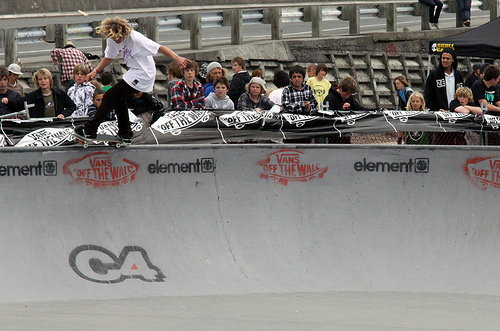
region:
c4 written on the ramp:
[37, 220, 212, 330]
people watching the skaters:
[167, 52, 378, 139]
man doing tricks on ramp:
[86, 10, 168, 170]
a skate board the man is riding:
[60, 119, 160, 151]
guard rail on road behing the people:
[154, 12, 334, 42]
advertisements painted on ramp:
[60, 155, 198, 193]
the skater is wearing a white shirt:
[100, 38, 157, 97]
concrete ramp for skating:
[173, 192, 419, 299]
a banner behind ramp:
[184, 117, 306, 138]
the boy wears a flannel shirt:
[172, 75, 204, 112]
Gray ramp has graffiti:
[1, 148, 498, 328]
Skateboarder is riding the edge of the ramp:
[69, 14, 190, 151]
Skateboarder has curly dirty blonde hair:
[93, 13, 134, 43]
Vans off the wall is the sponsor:
[255, 145, 332, 187]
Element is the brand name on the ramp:
[145, 157, 220, 181]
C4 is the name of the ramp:
[64, 245, 166, 286]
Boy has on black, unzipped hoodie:
[423, 49, 470, 106]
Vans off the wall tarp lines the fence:
[3, 105, 499, 155]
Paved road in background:
[0, 14, 499, 46]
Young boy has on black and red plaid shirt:
[169, 76, 209, 111]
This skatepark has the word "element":
[151, 149, 223, 211]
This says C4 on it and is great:
[75, 235, 157, 313]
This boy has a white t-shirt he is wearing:
[121, 43, 138, 73]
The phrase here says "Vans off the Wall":
[266, 137, 333, 191]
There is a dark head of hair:
[290, 65, 307, 76]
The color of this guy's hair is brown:
[342, 72, 369, 94]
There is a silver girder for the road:
[40, 6, 55, 26]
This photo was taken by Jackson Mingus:
[70, 10, 376, 322]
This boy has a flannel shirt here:
[56, 38, 76, 73]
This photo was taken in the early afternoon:
[86, 18, 372, 283]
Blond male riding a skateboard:
[70, 12, 191, 147]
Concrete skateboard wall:
[0, 140, 496, 330]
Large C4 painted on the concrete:
[65, 236, 167, 286]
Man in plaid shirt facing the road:
[45, 36, 90, 86]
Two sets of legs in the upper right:
[415, 0, 485, 32]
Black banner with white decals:
[0, 105, 495, 146]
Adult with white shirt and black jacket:
[421, 42, 467, 107]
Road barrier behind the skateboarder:
[0, 0, 498, 71]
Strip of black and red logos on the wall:
[0, 146, 498, 191]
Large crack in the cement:
[205, 145, 252, 283]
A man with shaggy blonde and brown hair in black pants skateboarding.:
[72, 17, 192, 142]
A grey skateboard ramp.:
[0, 142, 499, 327]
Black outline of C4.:
[66, 242, 164, 285]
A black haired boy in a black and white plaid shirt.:
[282, 65, 316, 114]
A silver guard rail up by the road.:
[2, 0, 492, 31]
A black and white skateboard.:
[67, 130, 130, 148]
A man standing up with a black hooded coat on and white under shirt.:
[424, 46, 463, 109]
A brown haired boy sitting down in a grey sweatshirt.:
[203, 79, 235, 110]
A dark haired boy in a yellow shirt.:
[306, 63, 331, 103]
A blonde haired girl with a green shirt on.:
[399, 88, 431, 144]